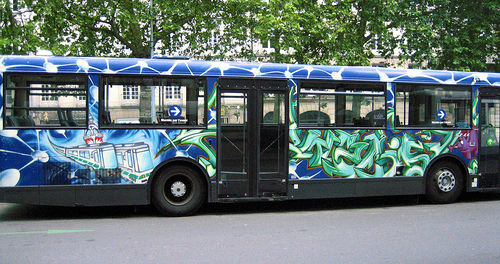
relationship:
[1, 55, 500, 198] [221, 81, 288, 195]
bus has doors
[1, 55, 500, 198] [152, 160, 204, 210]
bus has tire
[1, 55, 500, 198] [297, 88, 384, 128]
bus has window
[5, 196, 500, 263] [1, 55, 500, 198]
road under bus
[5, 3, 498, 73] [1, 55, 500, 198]
trees behind bus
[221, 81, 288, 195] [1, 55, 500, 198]
doors on bus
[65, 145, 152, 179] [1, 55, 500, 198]
train on bus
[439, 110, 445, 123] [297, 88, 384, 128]
arrow on window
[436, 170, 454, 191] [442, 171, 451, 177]
hubcap has dots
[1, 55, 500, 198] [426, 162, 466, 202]
bus has wheel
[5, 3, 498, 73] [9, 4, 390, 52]
trees have leaves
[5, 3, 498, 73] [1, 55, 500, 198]
trees over bus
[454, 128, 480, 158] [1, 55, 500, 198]
image on bus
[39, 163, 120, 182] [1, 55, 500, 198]
lines on bus